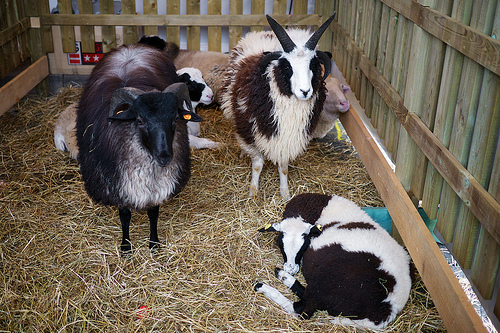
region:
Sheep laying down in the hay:
[237, 189, 431, 331]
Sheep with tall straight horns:
[244, 14, 345, 152]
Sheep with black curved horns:
[96, 73, 206, 177]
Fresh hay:
[16, 223, 116, 328]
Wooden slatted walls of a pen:
[357, 6, 490, 234]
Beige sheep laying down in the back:
[323, 71, 357, 134]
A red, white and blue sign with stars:
[66, 41, 106, 66]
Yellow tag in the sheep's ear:
[179, 109, 196, 126]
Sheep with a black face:
[108, 91, 203, 168]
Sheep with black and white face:
[267, 49, 325, 99]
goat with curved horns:
[76, 45, 196, 254]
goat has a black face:
[109, 91, 204, 166]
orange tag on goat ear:
[183, 113, 190, 120]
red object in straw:
[137, 304, 149, 314]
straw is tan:
[0, 77, 445, 331]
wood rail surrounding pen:
[339, 104, 484, 331]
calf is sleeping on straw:
[249, 193, 415, 329]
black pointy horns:
[264, 12, 298, 51]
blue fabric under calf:
[363, 205, 395, 234]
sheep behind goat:
[174, 46, 349, 138]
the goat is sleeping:
[256, 162, 443, 322]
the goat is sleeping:
[279, 181, 363, 321]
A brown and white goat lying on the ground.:
[256, 190, 412, 328]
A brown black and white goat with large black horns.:
[219, 14, 332, 204]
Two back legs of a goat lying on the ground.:
[254, 264, 311, 322]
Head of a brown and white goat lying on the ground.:
[257, 216, 322, 276]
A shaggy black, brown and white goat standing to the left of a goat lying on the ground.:
[77, 44, 196, 251]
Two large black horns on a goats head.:
[261, 13, 336, 49]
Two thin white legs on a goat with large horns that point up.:
[241, 151, 291, 203]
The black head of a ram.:
[105, 84, 194, 166]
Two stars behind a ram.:
[79, 51, 100, 63]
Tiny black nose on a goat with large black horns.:
[298, 85, 311, 97]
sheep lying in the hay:
[243, 186, 418, 330]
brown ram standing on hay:
[67, 39, 213, 263]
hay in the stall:
[13, 258, 237, 328]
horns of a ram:
[261, 6, 343, 55]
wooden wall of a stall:
[386, 9, 498, 188]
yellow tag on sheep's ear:
[259, 219, 275, 239]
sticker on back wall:
[59, 34, 123, 71]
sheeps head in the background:
[322, 69, 360, 127]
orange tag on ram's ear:
[174, 110, 196, 129]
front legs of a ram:
[112, 207, 182, 256]